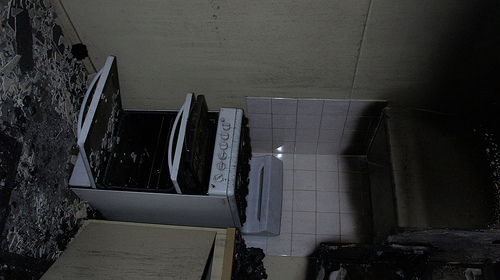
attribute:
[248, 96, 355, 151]
tile — white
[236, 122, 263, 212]
burners — black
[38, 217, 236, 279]
cabinet — beige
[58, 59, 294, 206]
stove — white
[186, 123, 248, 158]
knob — white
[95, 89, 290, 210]
stove — white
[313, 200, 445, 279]
cabinet — black, burned out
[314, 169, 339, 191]
tile — white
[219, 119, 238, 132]
knob — white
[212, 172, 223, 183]
knob — white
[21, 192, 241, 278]
cabinet — lower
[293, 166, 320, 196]
tile — tiled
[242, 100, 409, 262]
wall — white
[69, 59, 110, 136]
handle — white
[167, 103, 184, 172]
handle — white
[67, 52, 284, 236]
stove — white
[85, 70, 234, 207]
stove — white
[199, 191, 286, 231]
doors — open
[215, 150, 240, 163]
knob — white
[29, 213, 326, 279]
cabinet — old, brown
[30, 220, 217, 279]
door — open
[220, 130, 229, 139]
knob — white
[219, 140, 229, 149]
knob — white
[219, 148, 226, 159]
knob — white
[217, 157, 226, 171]
knob — white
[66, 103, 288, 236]
stove — white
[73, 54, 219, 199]
door — opened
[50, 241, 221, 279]
streaks — soot